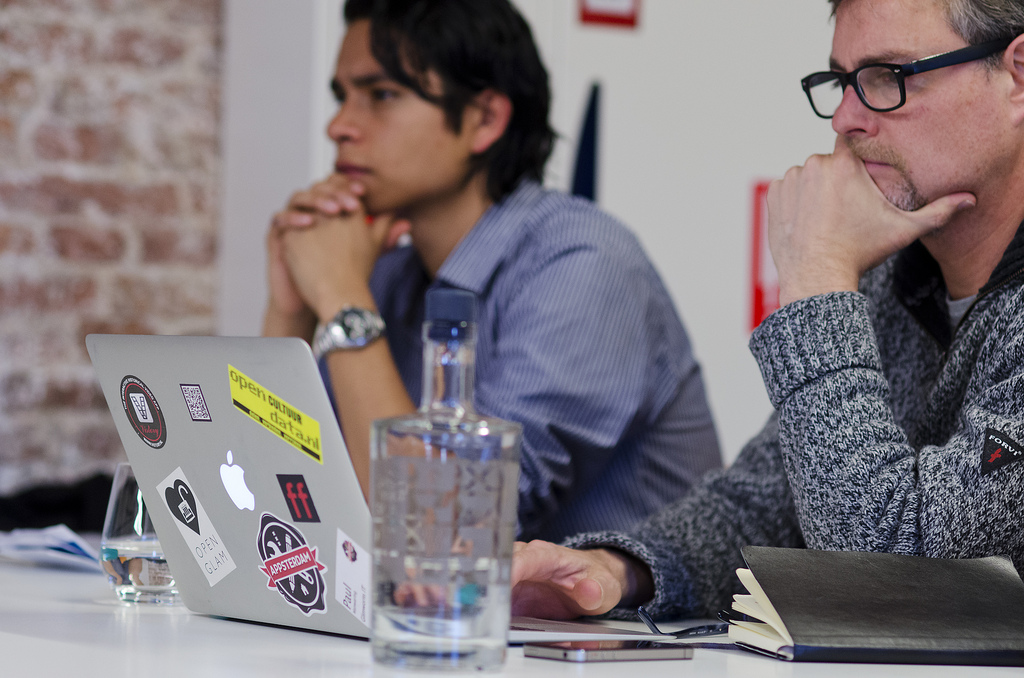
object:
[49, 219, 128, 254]
brick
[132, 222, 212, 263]
brick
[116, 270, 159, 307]
brick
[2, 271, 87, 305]
brick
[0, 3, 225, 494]
wall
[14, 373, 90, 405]
brick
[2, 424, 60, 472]
brick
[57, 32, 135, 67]
brick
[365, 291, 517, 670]
bottle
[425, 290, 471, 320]
cap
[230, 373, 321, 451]
sticker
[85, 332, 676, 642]
laptop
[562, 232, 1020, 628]
sweater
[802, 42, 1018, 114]
glasses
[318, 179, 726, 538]
button down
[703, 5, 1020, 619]
man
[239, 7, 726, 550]
man